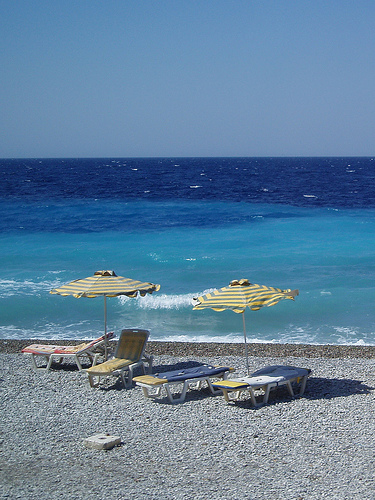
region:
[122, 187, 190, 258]
gradient blue beach water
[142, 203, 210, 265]
gradient blue beach water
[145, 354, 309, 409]
these are two beach chairs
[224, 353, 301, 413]
the chair is flat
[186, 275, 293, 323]
this is an umbrella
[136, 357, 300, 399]
the beach chairs are empty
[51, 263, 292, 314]
the umbrellas are two in number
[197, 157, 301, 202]
the sea is blue in color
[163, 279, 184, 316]
the waves are on the sea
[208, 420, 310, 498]
the stones are small in size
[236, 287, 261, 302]
the umbrella is yellow in color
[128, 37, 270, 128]
the sky is blue in color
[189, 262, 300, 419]
A beach umbrella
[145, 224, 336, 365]
A beach umbrella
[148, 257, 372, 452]
A beach umbrella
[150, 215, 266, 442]
A beach umbrella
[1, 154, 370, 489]
the beach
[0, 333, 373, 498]
the beach is covered with pebbles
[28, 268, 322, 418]
lounge chairs on the shore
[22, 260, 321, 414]
four lounge chairs with umbrellas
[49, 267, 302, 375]
the umbrellas are yellow and grey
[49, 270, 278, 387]
the umbrellas have a striped pattern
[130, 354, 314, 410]
blue towels are on the two right most chairs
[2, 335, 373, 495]
the sand is grey and stoney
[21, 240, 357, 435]
a seating area at the beach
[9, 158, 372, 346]
the ocean is blue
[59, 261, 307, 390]
There are two umbrellas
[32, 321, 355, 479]
The beach has large pebbles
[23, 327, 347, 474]
The rocks are grey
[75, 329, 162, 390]
The chair is yellow and white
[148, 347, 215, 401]
There is a blue towel on top of the chair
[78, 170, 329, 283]
The ocean is light blue near shore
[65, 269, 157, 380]
The chair is under the umbrella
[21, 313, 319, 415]
There are four chairs on the beach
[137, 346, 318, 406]
Two chairs are flat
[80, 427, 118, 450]
A square cement block